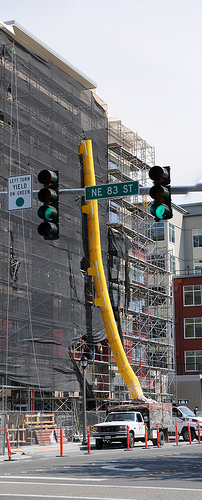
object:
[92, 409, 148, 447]
truck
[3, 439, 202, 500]
street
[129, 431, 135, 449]
wheel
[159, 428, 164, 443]
tire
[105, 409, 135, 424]
windshield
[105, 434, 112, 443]
license plate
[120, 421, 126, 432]
headlight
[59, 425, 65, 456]
traffic post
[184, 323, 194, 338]
windows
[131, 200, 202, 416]
building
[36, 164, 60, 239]
traffic signal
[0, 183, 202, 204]
pole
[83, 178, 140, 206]
street sign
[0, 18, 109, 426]
building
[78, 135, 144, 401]
tube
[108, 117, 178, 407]
scaffolding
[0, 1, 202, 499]
construction site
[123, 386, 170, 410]
garbage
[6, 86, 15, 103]
person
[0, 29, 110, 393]
mesh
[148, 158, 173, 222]
trafficlights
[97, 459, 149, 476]
arrow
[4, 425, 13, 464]
construction poles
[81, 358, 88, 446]
light post